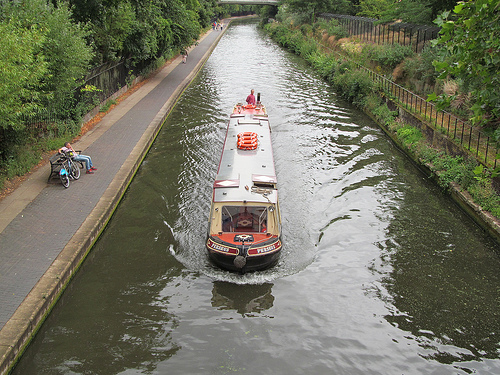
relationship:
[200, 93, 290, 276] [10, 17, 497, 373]
boat traveling on canal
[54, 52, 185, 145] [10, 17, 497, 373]
sidewalk running along canal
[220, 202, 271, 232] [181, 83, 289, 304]
window of boat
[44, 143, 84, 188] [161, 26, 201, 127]
bench on sidewalk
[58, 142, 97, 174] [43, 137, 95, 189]
man sitting on bench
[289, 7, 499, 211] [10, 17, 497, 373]
fence along canal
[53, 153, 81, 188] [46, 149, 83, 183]
bicycle leaning on bench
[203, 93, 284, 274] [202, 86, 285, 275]
boat on river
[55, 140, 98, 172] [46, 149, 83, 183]
man on bench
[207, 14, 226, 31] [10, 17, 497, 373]
people walking along canal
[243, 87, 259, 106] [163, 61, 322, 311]
man standing on boat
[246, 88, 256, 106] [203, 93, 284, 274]
man standing on back of boat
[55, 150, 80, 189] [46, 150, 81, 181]
bicycle resting against a bench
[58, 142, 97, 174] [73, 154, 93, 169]
man wearing blue jeans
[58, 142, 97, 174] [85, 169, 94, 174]
man wearing red shoe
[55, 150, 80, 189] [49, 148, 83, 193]
bicycle leaning against bench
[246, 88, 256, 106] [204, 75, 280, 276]
man standing on back of boat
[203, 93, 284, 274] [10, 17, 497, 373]
boat floating down canal